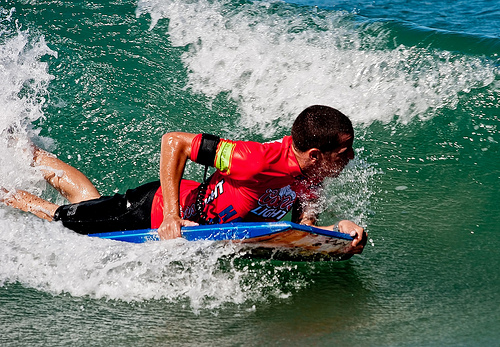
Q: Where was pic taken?
A: The ocean.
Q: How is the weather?
A: Sunny.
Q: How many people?
A: One.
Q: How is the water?
A: Lots of waves.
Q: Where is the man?
A: In the ocean.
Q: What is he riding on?
A: A bodyboard.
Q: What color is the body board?
A: Blue.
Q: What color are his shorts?
A: Black.